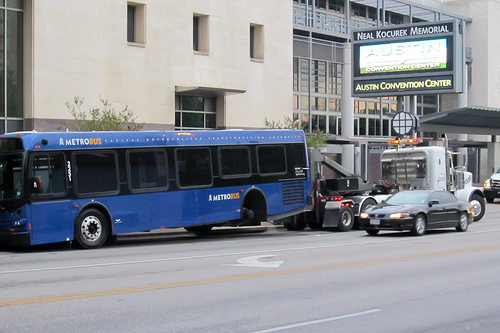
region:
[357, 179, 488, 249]
car is small and black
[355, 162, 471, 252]
car is small and black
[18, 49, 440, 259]
bus on city street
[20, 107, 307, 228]
royal blue metro bus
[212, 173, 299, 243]
bus missing wheel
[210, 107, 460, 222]
blue bus is being towed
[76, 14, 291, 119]
bus is in front of beige office building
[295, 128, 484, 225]
tow truck to pull the bus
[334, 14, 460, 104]
sign above marquis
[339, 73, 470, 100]
sign indicates Austin Convention Center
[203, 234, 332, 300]
white arrow on street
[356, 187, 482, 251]
grey car with lights on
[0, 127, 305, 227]
this is a bus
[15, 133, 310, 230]
the bus is long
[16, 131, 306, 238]
the bus is blue in color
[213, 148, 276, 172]
the windows are tinted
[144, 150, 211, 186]
the windows are closed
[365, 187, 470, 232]
a car is beside the bus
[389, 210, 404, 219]
the front blight is on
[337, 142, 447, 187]
a trailer is behind the bus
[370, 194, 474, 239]
the car is black in color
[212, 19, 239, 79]
the building is tall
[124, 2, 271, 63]
windows in a stone building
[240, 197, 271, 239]
bus missin a wheel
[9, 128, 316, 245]
a blue city bus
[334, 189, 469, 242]
black car with four tires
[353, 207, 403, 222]
bright headlights on a car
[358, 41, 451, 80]
a marquee hanging over the street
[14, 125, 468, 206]
a white tow truck towing a bus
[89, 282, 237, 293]
yellow lines in the stree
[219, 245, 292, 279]
a white arrow on the street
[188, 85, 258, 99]
a wooden awning over a window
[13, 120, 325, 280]
Blue bus in the street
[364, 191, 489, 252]
Black car driving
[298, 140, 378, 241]
Truck lifting bus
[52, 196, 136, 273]
Black tires with silver rims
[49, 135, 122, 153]
The words "A Metro Bus"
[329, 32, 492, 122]
sign for Austin convention center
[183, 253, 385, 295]
Left turn lane in street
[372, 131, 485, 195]
Truck with orange lights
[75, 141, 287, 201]
Windows on bus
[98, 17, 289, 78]
Windows on building